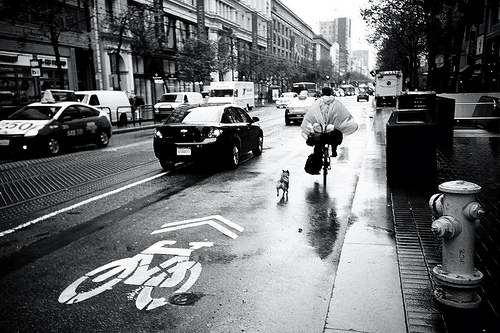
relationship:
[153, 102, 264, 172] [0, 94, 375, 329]
car driving down street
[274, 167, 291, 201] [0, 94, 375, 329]
dog walking down street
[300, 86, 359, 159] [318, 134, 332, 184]
person on bicycle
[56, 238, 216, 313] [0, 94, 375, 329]
bicycle painted on street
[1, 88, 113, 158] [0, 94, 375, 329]
taxi driving down street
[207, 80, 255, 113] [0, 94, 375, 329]
truck driving down street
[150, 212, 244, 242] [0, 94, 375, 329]
arrows painted on street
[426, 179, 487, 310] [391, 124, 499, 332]
fire hydrant on sidewalk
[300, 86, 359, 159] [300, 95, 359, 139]
person wearing raincoat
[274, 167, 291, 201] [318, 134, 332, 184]
dog chasing bicycle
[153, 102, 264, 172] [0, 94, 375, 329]
car on street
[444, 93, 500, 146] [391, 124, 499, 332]
subway entrance next to sidewalk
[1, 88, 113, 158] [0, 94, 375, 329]
taxi on street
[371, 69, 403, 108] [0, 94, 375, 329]
truck parked by street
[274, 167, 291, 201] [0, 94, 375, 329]
dog running down street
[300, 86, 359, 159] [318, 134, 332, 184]
person riding bicycle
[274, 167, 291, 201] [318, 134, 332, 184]
dog running beside bicycle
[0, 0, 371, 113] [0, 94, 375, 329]
buildings next to street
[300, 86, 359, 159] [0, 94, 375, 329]
person riding in street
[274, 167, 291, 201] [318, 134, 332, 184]
dog following bicycle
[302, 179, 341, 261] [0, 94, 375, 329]
reflection on street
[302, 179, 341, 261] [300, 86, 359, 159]
reflection of person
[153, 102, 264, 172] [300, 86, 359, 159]
car next to person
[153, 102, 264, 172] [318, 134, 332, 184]
car next to bicycle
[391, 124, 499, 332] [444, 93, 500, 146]
sidewalk leads to subway entrance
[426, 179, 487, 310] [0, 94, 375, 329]
fire hydrant next to street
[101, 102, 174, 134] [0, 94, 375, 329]
fences on street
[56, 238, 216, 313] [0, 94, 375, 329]
bicycle on street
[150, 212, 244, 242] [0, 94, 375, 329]
arrows on street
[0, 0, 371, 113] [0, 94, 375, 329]
buildings by street